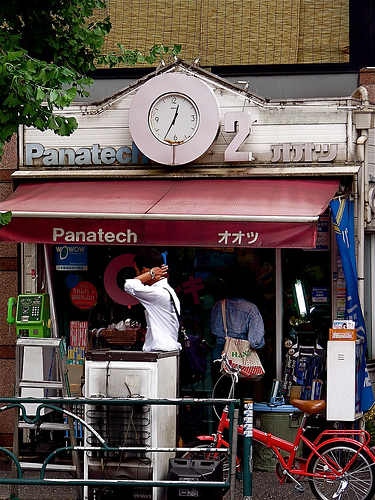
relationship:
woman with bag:
[216, 297, 265, 379] [221, 331, 270, 378]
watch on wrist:
[146, 267, 156, 280] [144, 267, 164, 284]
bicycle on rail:
[181, 377, 374, 495] [0, 393, 243, 500]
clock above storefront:
[147, 90, 202, 147] [0, 57, 373, 458]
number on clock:
[171, 94, 181, 106] [143, 88, 202, 150]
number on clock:
[184, 110, 198, 124] [143, 88, 202, 150]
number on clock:
[166, 131, 183, 144] [143, 88, 202, 150]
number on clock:
[146, 111, 160, 125] [143, 88, 202, 150]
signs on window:
[53, 245, 88, 269] [47, 242, 147, 351]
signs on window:
[65, 274, 77, 287] [47, 242, 147, 351]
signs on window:
[72, 282, 97, 307] [47, 242, 147, 351]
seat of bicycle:
[286, 394, 327, 414] [181, 435, 374, 497]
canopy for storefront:
[0, 170, 342, 251] [15, 60, 362, 471]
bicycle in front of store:
[170, 349, 375, 500] [1, 177, 352, 498]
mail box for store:
[326, 334, 361, 425] [12, 125, 367, 498]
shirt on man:
[128, 275, 183, 351] [122, 254, 191, 353]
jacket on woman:
[205, 296, 265, 358] [209, 269, 266, 458]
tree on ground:
[2, 2, 193, 158] [0, 465, 375, 500]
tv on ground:
[167, 456, 223, 498] [8, 430, 363, 496]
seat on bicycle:
[286, 394, 326, 416] [170, 349, 375, 500]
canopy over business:
[0, 170, 356, 249] [3, 63, 360, 451]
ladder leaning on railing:
[7, 323, 86, 498] [6, 391, 245, 493]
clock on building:
[147, 90, 202, 147] [4, 62, 363, 469]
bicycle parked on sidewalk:
[170, 349, 375, 500] [0, 438, 360, 491]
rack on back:
[314, 425, 371, 437] [302, 433, 361, 493]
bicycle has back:
[170, 349, 375, 500] [302, 433, 361, 493]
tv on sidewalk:
[167, 456, 223, 498] [0, 412, 371, 497]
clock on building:
[147, 90, 202, 147] [0, 1, 372, 466]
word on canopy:
[47, 223, 141, 243] [0, 170, 342, 251]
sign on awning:
[245, 228, 259, 244] [150, 175, 300, 252]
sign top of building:
[21, 128, 150, 194] [11, 101, 365, 463]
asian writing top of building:
[265, 140, 340, 166] [4, 62, 363, 469]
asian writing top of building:
[214, 224, 261, 246] [4, 62, 363, 469]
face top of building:
[309, 136, 348, 168] [4, 62, 363, 469]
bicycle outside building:
[170, 349, 375, 500] [4, 62, 363, 469]